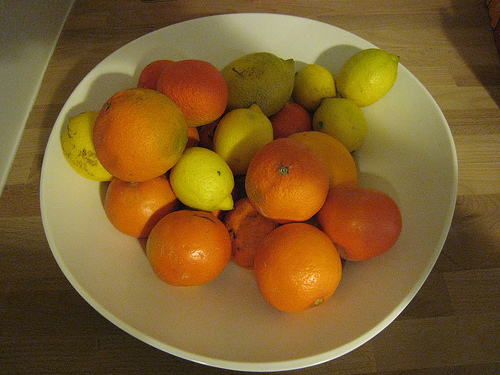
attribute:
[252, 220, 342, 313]
orange — round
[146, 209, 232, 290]
orange — round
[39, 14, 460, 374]
plate — white, round, large, ceramic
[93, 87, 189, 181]
orange — round, large, green, spotted, stemed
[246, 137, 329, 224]
orange — round, stemed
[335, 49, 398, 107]
lemon — small, spotted, yellow, pointed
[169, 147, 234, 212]
lemon — spotted, pointed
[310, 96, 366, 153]
lemon — pointed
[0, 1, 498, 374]
table — brown, wood, wooden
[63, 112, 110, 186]
lemon — rotted